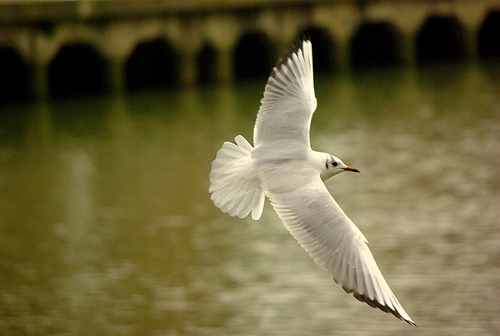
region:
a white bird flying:
[216, 26, 416, 318]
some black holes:
[38, 39, 251, 94]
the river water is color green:
[38, 168, 156, 297]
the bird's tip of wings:
[268, 27, 327, 74]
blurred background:
[380, 184, 445, 254]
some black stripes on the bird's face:
[321, 144, 336, 173]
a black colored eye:
[331, 157, 339, 172]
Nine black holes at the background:
[1, 5, 496, 127]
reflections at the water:
[41, 77, 252, 133]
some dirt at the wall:
[16, 18, 64, 63]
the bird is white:
[191, 31, 421, 333]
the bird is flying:
[191, 47, 373, 296]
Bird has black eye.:
[325, 156, 340, 170]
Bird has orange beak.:
[341, 163, 367, 182]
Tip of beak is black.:
[350, 166, 365, 178]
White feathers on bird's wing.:
[349, 250, 404, 306]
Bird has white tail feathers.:
[210, 170, 239, 207]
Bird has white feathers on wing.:
[255, 90, 293, 132]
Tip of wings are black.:
[274, 28, 317, 49]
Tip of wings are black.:
[353, 280, 417, 324]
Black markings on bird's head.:
[322, 148, 336, 178]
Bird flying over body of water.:
[176, 85, 407, 269]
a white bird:
[203, 30, 445, 323]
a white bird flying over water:
[206, 22, 407, 297]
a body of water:
[45, 112, 476, 322]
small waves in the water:
[28, 140, 238, 320]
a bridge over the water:
[12, 11, 489, 72]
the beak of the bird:
[342, 158, 362, 178]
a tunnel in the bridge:
[40, 30, 121, 96]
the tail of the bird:
[200, 108, 266, 219]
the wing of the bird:
[279, 185, 421, 330]